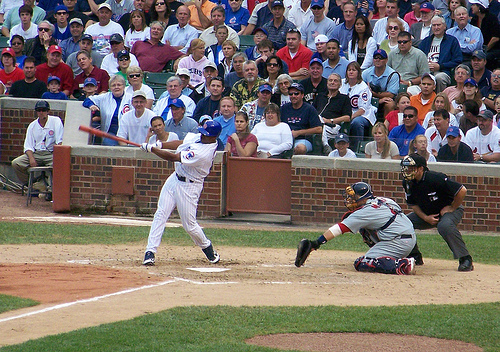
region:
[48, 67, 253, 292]
Baseball player on the field.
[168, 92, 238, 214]
Man wearing a helmet.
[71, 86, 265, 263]
Man with a baseball bat.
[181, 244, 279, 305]
Plate on the ground.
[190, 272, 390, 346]
Grass on the ground.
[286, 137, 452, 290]
Catcher in the background.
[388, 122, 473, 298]
Umpire in the background.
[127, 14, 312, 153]
People in the crowd.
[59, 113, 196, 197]
Bricks on the wall.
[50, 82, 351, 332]
Man in a white uniform.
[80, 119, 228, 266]
baseball player swinging baseball bat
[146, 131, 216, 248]
white baseball uniform with stripes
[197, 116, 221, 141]
blue hard plastic helmet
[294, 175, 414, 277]
catcher catching a baseball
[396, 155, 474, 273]
umpire squatting down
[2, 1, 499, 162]
crowd watching baseball game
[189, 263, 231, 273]
home plate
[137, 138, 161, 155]
small white baseball gloves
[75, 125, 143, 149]
a red baseball bat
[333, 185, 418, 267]
a grey and red baseball uniform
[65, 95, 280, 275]
baseball player wearing a safety helmet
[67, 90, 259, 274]
baseball player swinging a bat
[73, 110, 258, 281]
baseball player wearing a white uniform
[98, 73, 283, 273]
baseball player wearing black shoes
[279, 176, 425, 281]
catcher wearing a safety helmet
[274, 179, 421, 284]
catcher holding a black leather glove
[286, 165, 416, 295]
catcher wearing black knee guards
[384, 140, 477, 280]
umpire wearing gray pants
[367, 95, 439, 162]
man wearing black sunglasses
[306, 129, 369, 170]
little boy wearing baseball cap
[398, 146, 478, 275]
baseball umpire crouches behind the catcher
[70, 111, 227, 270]
baseball batter swings and missed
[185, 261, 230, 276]
baseball diamond home plate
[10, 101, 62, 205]
staff at the baseball stadium sits on a stool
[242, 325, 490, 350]
baseball warm-up circle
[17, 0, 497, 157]
spectators in baseball stadium stands watching the game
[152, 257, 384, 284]
batters box in baseball stadium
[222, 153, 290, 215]
brown metal gate between baseball field and stands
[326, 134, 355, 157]
young boy watching baseball game from front row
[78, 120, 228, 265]
a baseball player swinging a baseball bat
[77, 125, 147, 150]
a long red baseball bat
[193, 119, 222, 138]
a hard, blue, protective helmet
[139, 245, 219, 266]
a pair of black and white shoes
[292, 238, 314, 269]
a black baseball glove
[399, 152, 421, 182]
a light colored umpire mask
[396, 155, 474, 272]
an umpire squatting down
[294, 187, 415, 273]
a catcher catching a baseball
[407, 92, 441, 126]
an orange collard shirt